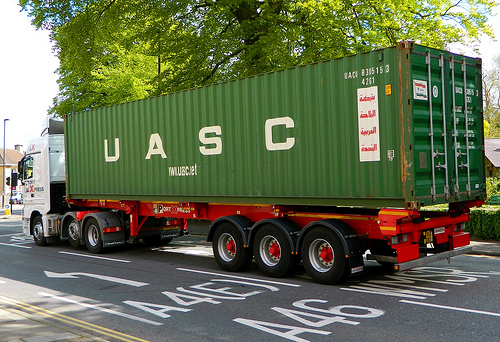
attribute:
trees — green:
[82, 17, 142, 72]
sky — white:
[1, 22, 48, 101]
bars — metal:
[426, 49, 471, 201]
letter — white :
[97, 133, 127, 165]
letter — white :
[139, 124, 175, 160]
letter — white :
[188, 120, 227, 160]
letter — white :
[258, 109, 303, 154]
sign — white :
[356, 85, 378, 161]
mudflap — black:
[343, 239, 374, 284]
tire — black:
[251, 222, 300, 276]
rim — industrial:
[67, 221, 80, 242]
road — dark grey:
[68, 270, 133, 303]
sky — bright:
[8, 8, 113, 113]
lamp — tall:
[0, 103, 17, 242]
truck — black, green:
[20, 40, 486, 283]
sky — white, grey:
[6, 18, 275, 111]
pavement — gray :
[145, 270, 279, 327]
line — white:
[177, 266, 299, 286]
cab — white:
[19, 116, 64, 236]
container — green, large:
[64, 40, 486, 208]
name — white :
[93, 110, 304, 181]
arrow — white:
[42, 262, 149, 296]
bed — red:
[63, 197, 483, 265]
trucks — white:
[62, 37, 488, 208]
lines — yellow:
[21, 300, 101, 336]